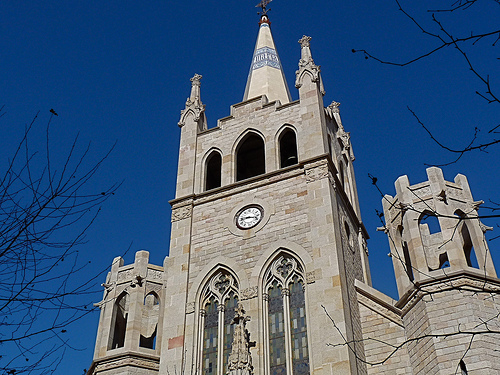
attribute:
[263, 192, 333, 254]
tower wall — brown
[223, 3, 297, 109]
tower — stained glass window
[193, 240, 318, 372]
windows — stained glass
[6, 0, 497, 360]
blue sky — clear , blue 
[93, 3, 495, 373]
stone church — white , stone 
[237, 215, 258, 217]
black hands — black 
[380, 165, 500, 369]
tower — on the right side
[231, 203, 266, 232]
clock — white